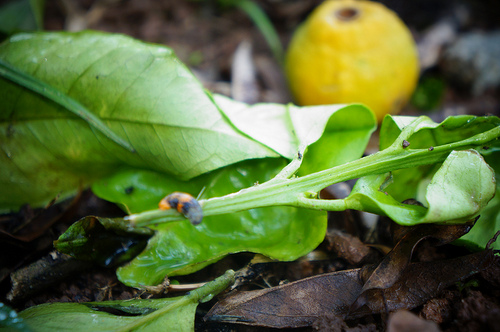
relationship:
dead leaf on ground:
[217, 277, 375, 327] [408, 276, 495, 328]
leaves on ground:
[0, 28, 500, 332] [353, 262, 405, 312]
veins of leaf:
[35, 43, 159, 114] [0, 30, 332, 262]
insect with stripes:
[158, 187, 207, 227] [157, 193, 192, 209]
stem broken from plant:
[40, 208, 144, 247] [139, 100, 424, 271]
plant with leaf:
[139, 100, 424, 271] [1, 31, 377, 291]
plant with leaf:
[139, 100, 424, 271] [355, 115, 498, 225]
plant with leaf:
[139, 100, 424, 271] [16, 267, 233, 329]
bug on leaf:
[123, 186, 135, 195] [118, 141, 340, 262]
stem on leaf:
[116, 136, 463, 226] [187, 86, 491, 250]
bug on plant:
[159, 192, 201, 223] [2, 31, 499, 288]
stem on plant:
[10, 255, 62, 298] [4, 22, 496, 330]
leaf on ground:
[7, 266, 246, 332] [7, 13, 498, 329]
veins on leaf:
[83, 61, 190, 145] [3, 24, 335, 201]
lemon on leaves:
[277, 2, 428, 116] [6, 31, 498, 258]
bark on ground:
[324, 227, 372, 263] [2, 187, 497, 328]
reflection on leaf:
[193, 77, 350, 158] [1, 31, 377, 291]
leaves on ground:
[0, 28, 500, 332] [32, 221, 492, 324]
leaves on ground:
[5, 28, 281, 208] [32, 221, 492, 324]